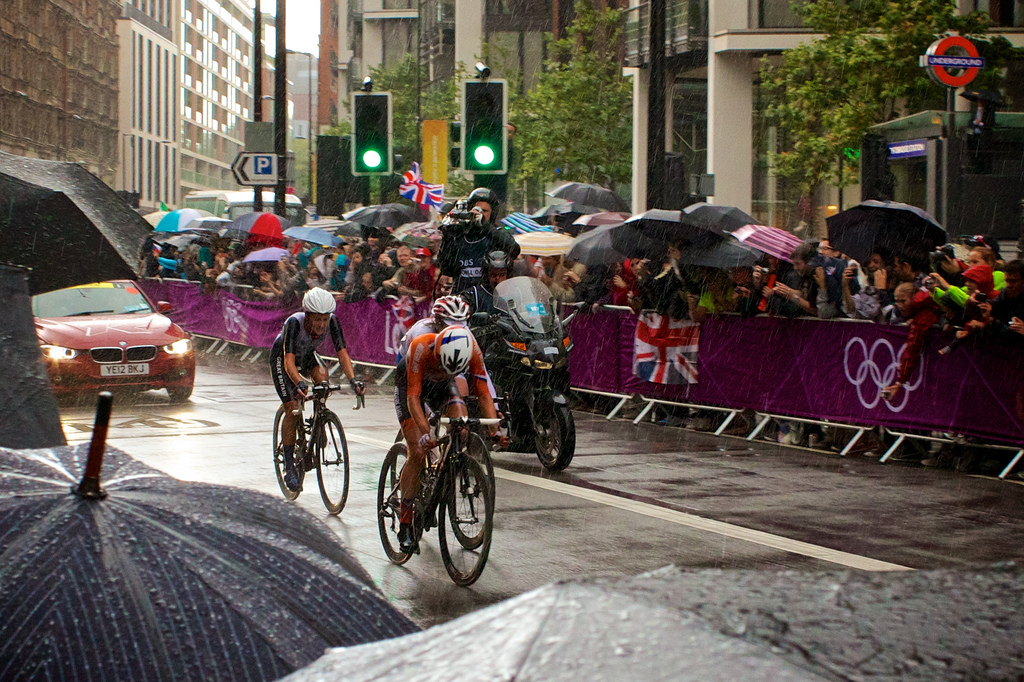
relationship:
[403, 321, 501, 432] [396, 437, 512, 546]
man on bike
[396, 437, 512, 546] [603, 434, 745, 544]
bike on road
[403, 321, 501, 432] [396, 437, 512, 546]
man riding bike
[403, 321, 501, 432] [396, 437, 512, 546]
man on a bike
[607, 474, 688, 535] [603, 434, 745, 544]
line on road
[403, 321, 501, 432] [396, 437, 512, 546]
man near bike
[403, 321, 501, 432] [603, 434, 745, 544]
man on road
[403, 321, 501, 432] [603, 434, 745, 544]
man in road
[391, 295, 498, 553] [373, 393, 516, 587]
man riding bike